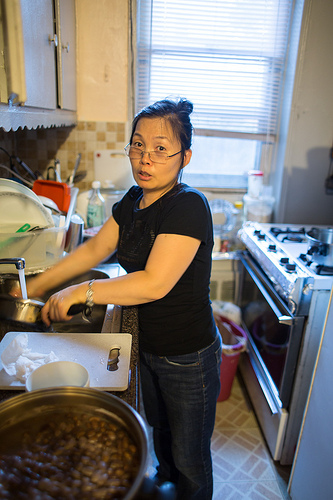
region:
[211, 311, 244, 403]
The bin is red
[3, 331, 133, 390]
The cutting board is white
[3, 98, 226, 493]
The woman is washing a pan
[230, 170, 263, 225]
The bottles have red and yellow lids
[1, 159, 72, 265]
Pans, bowls, and cooking utensils piled on top of each other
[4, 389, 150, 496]
Brown beans in a pot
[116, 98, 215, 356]
The woman is wearing a black shirt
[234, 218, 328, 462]
The oven is silver and black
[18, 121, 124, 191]
The tile back splash is different shades of brown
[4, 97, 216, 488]
The woman is standing by the sink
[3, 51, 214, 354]
woman washing dishes by hand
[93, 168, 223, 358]
woman wearing a black shirt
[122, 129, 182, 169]
woman wearing glasses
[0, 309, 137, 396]
white cutting board on counter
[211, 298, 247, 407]
pink plastic garbage bin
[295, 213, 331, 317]
pot on white stove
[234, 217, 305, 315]
aluminum foil on stove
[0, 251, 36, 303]
water coming from faucet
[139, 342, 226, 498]
woman wearing blue jeans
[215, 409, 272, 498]
patterned tile kitchen floor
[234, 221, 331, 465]
a stove in a kitchen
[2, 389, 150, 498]
beans in a pot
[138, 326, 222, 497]
a woman wearing blue jeans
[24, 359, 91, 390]
a white plastic container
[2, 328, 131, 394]
a white cutter board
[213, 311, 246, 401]
a red wastebasket on the floor of a kitchen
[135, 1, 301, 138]
blinds on a window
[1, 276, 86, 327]
a woman washing a pan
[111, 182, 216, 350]
a woman wearing a black shirt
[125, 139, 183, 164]
a woman wearing glasses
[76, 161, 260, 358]
a woman wearing a black shirt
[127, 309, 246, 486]
a woman wearing blue jeans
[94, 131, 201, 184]
a woman wearing glasses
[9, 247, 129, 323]
a woman wearing washing a pot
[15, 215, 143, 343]
a woman wearing holding a pot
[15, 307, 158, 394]
a white cutting board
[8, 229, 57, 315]
a fosset in the kitchen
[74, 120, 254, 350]
a woman standing in a kitchen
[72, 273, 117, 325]
woman wearing a bracelet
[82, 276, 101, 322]
woman wearing a bracelet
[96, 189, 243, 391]
the shirt is black